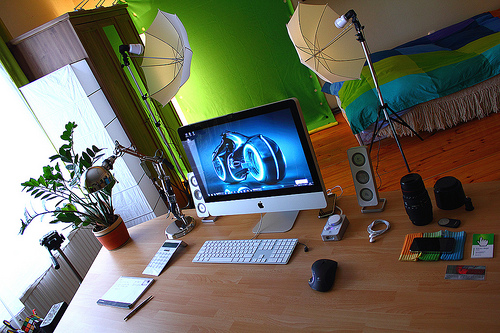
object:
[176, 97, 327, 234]
monitor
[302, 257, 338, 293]
mouse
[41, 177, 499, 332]
desk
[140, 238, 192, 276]
calculator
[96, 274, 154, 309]
notepad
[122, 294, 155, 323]
pen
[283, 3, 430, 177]
lights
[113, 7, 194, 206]
lights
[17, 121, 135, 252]
houseplant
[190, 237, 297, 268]
keyboard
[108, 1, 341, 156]
backdrop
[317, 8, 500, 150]
bedspread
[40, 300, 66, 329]
cube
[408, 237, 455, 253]
iphone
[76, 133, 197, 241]
lamp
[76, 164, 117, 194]
head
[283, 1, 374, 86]
umbrella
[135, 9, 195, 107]
umbrella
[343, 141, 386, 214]
speakers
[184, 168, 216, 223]
speakers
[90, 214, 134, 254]
pot